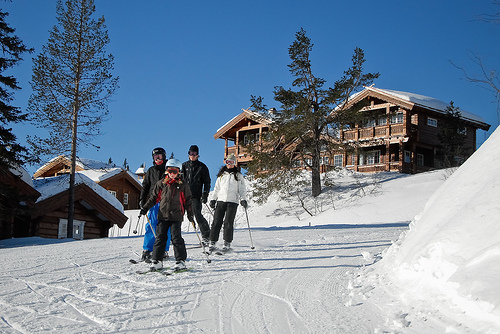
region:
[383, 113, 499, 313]
Hillside covered with snow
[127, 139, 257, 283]
The skiers on the slope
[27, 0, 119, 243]
The tree with the least leaves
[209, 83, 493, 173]
The large buildings behind the people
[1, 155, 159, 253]
The building to the people's right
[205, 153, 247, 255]
The person with the white jacket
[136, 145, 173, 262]
The skier with the blue pants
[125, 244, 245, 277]
The skis of the people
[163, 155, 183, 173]
The blue helmet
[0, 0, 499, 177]
The blue sky above the buildings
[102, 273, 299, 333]
tracks in fresh white snow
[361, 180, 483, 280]
mound of white snow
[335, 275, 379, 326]
small pieces of snow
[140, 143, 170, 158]
black cap on man's head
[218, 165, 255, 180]
black fur on white jacket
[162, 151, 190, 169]
white helmet on girl's head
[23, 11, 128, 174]
large green tree in yard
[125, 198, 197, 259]
man wearing blue pants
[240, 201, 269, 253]
ski pole in woman's hand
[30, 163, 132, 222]
white fresh snow on roof top of house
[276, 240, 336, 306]
the snow is white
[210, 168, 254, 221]
the jacket is white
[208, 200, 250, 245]
the pants are black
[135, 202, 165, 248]
the pants is blue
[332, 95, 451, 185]
the house is brown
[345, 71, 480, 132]
the roof is covered in snow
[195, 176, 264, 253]
the person holding a ski poles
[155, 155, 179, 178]
the kid is wearing a helmet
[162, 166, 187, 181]
the boy is wearing goggles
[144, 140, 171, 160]
the helmet is black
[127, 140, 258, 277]
Group of four people skiing.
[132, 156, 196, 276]
Child skiing down a hill.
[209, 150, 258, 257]
Woman in white jacket holding ski poles.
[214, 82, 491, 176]
Ski lodge at the top of the mountain.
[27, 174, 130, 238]
Smaller structure on the slope.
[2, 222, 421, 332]
Slope covered in snow and ski tracks.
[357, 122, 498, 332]
Mound of snow on the side of the path.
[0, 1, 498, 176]
Clear blue sky.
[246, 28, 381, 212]
Tree in front of the lodge.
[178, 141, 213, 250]
Man in black skiing down the slope.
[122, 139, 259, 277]
Family out snow skiing.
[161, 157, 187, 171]
Young girl wearing blue helmet.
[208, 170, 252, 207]
Woman dressed in white jacket.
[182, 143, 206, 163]
Man wearing black cap and goggles.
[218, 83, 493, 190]
House built on mountain top.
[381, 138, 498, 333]
Snow mounded on side of road.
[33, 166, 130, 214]
A snow covered roof.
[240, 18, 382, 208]
Pine tree growing in front of house.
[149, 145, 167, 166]
Young man wearing black helmet and goggles.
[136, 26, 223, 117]
A clear blue sky.